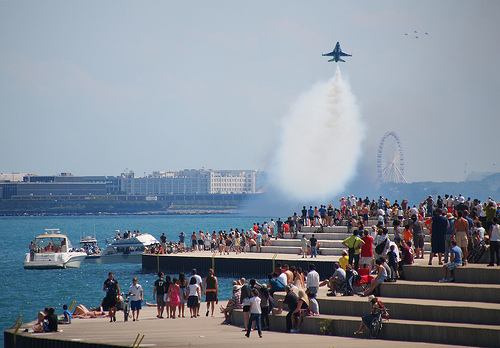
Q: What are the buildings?
A: Hotels.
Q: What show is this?
A: Air show.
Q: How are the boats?
A: Anchored.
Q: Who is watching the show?
A: Spectators.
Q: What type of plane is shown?
A: Jet.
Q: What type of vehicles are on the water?
A: Boats.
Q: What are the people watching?
A: Jet.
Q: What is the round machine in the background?
A: Ferris wheel.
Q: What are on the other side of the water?
A: Buildings.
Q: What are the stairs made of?
A: Cement.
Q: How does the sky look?
A: Grey.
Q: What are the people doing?
A: Watching.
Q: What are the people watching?
A: The jet.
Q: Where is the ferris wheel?
A: Across the body of water.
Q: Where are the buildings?
A: Across the body of water.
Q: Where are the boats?
A: In the water.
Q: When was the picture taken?
A: During day hours.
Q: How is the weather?
A: Hazy.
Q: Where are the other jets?
A: In unison in the sky in the distance.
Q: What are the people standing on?
A: A dock.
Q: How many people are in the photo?
A: Crowd.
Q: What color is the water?
A: Blue.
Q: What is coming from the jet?
A: Steam.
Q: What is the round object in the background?
A: Ferris wheel.